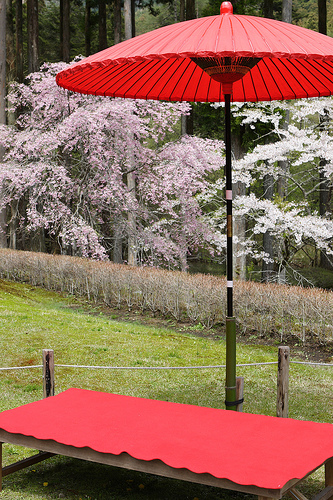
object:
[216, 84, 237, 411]
pole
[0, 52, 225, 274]
tree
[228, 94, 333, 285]
tree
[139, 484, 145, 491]
flower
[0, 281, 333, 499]
lawn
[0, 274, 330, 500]
grass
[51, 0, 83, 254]
tree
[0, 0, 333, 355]
background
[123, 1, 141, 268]
tree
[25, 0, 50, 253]
tree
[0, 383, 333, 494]
barrier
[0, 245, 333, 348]
bush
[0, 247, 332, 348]
row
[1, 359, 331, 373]
rope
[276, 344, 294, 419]
post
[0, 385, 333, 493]
covering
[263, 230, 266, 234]
blossom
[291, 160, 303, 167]
blossom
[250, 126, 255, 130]
blossom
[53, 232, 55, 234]
flowers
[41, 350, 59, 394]
post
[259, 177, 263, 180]
flower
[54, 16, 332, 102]
fabric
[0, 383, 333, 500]
stage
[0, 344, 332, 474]
fence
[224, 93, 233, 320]
metal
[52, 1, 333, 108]
canopy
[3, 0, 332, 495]
scene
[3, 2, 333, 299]
forest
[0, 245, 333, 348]
hedge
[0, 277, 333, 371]
edge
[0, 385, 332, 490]
red